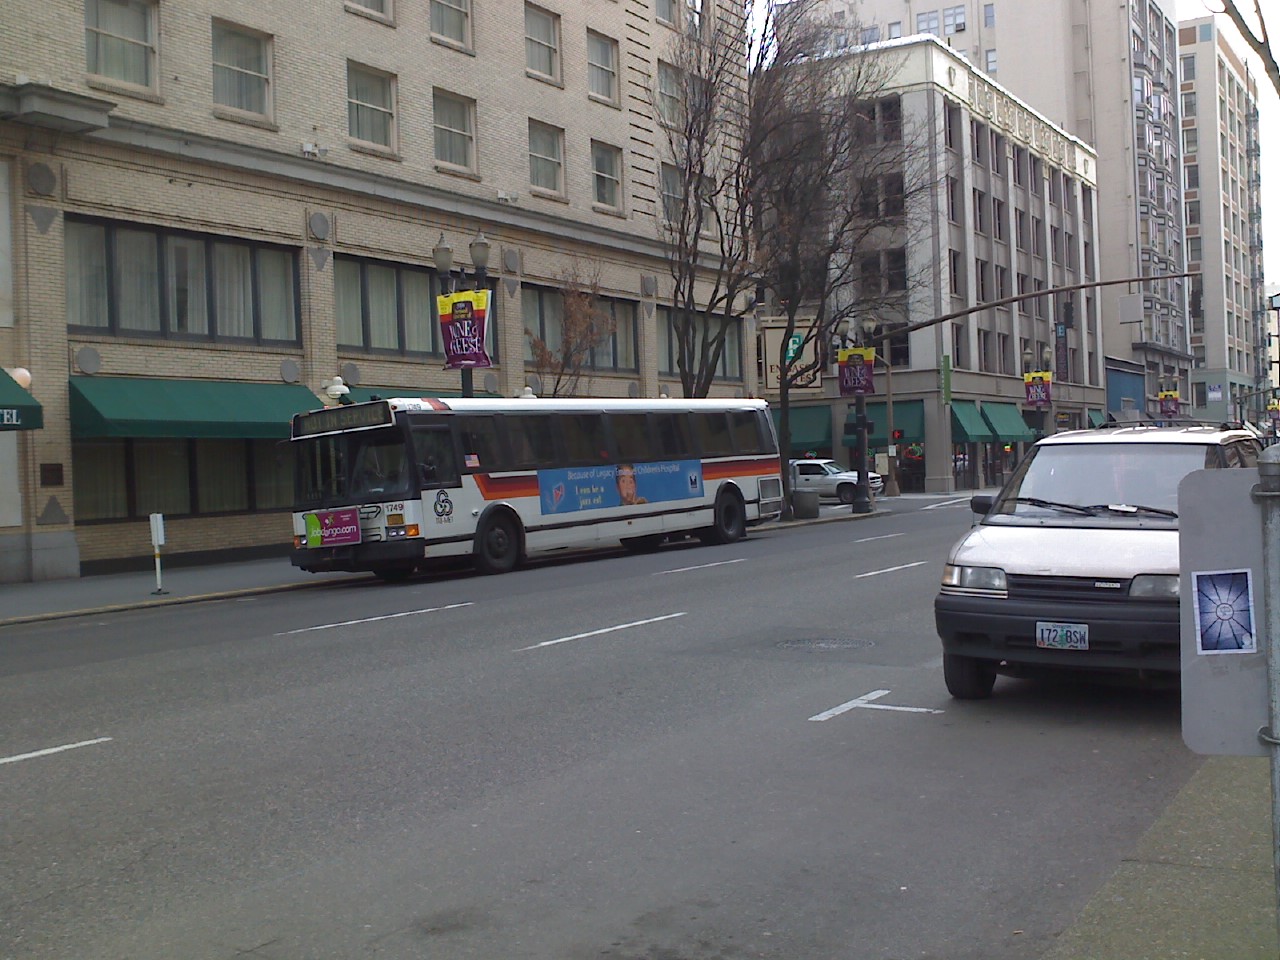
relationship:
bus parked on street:
[285, 377, 806, 579] [8, 484, 1206, 951]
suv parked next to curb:
[929, 412, 1278, 709] [1036, 624, 1240, 954]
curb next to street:
[29, 559, 345, 614] [29, 478, 1241, 924]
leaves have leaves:
[656, 19, 879, 351] [655, 19, 878, 351]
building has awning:
[18, 11, 781, 569] [73, 371, 329, 454]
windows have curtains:
[64, 201, 310, 361] [61, 212, 305, 353]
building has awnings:
[746, 28, 1118, 495] [950, 396, 1036, 454]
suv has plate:
[929, 412, 1278, 709] [1030, 613, 1104, 668]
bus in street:
[285, 377, 806, 579] [29, 478, 1241, 924]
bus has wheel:
[286, 377, 808, 579] [478, 503, 531, 577]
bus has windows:
[286, 377, 808, 579] [408, 401, 780, 461]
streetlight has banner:
[434, 280, 494, 394] [434, 285, 496, 378]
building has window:
[18, 11, 781, 569] [583, 136, 643, 217]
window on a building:
[205, 11, 279, 122] [0, 2, 751, 607]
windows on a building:
[65, 201, 311, 361] [0, 2, 751, 607]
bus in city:
[285, 377, 806, 579] [8, 5, 1278, 942]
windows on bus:
[392, 405, 799, 484] [285, 377, 806, 579]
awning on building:
[978, 391, 1036, 449] [746, 28, 1118, 495]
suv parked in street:
[929, 412, 1278, 709] [8, 484, 1206, 951]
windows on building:
[65, 201, 311, 361] [18, 11, 781, 569]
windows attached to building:
[65, 201, 311, 361] [18, 11, 781, 569]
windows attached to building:
[65, 201, 311, 361] [34, 35, 822, 570]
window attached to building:
[325, 223, 373, 341] [34, 35, 822, 570]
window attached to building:
[604, 284, 662, 395] [18, 11, 781, 569]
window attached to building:
[863, 76, 921, 143] [781, 39, 1123, 457]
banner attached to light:
[1018, 343, 1073, 438] [430, 223, 516, 388]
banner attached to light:
[1018, 343, 1073, 438] [835, 258, 1121, 472]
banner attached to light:
[1018, 342, 1073, 437] [1004, 332, 1080, 432]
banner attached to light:
[1018, 343, 1073, 438] [1095, 332, 1176, 415]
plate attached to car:
[1025, 612, 1106, 656] [949, 402, 1232, 704]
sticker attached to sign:
[1193, 565, 1260, 662] [1172, 453, 1262, 809]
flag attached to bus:
[432, 439, 494, 508] [286, 377, 808, 579]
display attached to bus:
[271, 395, 408, 450] [286, 377, 808, 579]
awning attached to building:
[39, 360, 327, 492] [18, 11, 781, 569]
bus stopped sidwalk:
[286, 377, 808, 579] [19, 570, 279, 621]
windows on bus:
[392, 405, 800, 483] [296, 360, 789, 611]